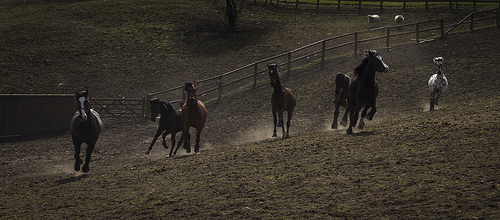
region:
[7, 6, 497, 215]
Photo was taken in the daytime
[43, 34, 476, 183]
Horses are running towards the camera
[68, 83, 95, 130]
Horse has a white stripe on its face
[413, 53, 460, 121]
The horse has a white and black colored coat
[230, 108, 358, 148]
Horses are kicking up dust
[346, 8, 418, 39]
Sheep are in the background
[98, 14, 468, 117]
A wooden fence is in the background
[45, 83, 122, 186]
Front view of a horse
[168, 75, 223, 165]
The horse has a copper brown colored coat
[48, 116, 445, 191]
Horses are running on dirt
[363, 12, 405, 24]
Two sheep in a pen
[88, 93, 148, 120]
Closed door of a fence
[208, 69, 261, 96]
Wooden fence in a an animal pen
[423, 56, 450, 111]
Black and white horse running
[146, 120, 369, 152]
Dust kicked up by running horses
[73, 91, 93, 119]
Brown horse with a white patch on head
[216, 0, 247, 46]
Tree trunk in an animal pen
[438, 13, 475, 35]
Broken pole on a wooden fence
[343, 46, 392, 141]
Dark colored horse running right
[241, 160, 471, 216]
Dry dirt in an animal pen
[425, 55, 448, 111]
A white and black horse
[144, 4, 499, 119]
A long wooden fence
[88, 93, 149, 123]
A large wooden fence gate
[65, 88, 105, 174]
A horse running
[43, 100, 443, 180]
Kicked up dust from horses running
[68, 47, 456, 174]
A group of seven horses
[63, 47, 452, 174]
A group of horses running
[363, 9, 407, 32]
Two sheep in the background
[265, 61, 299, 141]
A brown horse running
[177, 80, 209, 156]
A brown horse running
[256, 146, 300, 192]
part of a ground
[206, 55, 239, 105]
part of a fence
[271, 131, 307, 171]
part of a ground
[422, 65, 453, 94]
chest of a horse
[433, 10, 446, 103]
part of a horse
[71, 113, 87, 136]
head of a horse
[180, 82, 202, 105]
head of a horse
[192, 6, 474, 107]
two tiered wooden fence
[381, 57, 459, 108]
white horse running in pasture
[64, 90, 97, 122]
white blaze on horses face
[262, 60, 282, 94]
brown and white horses head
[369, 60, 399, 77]
brown and white horses nose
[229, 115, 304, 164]
brown horses hooves running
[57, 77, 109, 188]
brown and white horse running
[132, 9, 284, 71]
dark shadow of tree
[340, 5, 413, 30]
white horses in back round of picture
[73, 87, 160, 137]
wooden gate for the fence